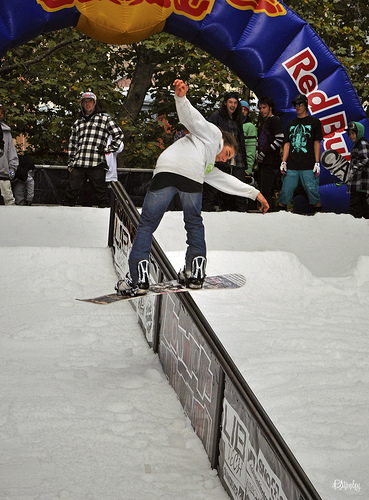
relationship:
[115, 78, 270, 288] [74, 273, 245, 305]
man on board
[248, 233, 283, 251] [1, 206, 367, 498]
snow on ground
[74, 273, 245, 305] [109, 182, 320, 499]
board on rail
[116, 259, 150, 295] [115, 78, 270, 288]
boot on man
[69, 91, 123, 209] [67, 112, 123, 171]
person in jacket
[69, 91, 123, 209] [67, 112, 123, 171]
person with jacket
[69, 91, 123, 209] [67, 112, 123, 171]
person wearing jacket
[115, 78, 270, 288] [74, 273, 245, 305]
man riding board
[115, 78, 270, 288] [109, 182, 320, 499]
man balancing down rail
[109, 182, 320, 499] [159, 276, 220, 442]
rail displaying sign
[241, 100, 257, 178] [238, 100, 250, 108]
person wearing hat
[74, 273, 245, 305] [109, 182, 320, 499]
board balancing on rail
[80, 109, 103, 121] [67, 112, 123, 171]
fur on jacket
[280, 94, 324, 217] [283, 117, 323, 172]
man wearing black and green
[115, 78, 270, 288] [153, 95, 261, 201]
man wearing shirt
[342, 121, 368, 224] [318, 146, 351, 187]
boy holding board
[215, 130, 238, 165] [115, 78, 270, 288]
head of man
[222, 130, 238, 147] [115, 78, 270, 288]
hair of man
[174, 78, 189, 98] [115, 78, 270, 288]
hand of man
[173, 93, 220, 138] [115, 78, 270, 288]
arm of man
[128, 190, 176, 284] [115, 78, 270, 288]
leg of man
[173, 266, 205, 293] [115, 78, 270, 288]
foot of man